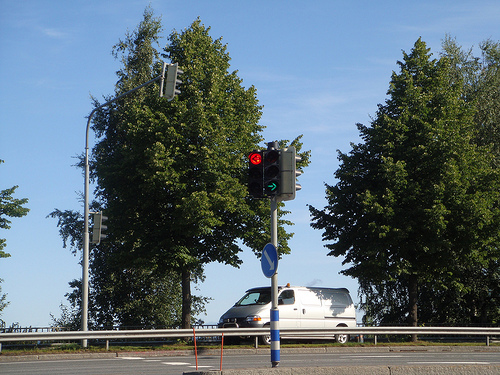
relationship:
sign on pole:
[259, 241, 279, 276] [263, 201, 281, 368]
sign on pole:
[259, 241, 279, 276] [79, 136, 94, 351]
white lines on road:
[118, 352, 210, 372] [0, 342, 497, 373]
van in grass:
[211, 277, 358, 345] [4, 337, 499, 344]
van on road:
[211, 277, 358, 345] [2, 315, 495, 368]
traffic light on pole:
[244, 146, 296, 203] [269, 201, 289, 366]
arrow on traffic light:
[264, 182, 277, 192] [216, 127, 293, 229]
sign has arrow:
[259, 241, 279, 276] [253, 234, 291, 279]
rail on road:
[4, 323, 498, 352] [10, 322, 472, 374]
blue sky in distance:
[1, 0, 498, 331] [6, 10, 498, 340]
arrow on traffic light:
[264, 182, 277, 192] [247, 145, 303, 200]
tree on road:
[101, 5, 312, 342] [2, 341, 499, 374]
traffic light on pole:
[159, 60, 178, 99] [78, 85, 153, 352]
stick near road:
[189, 321, 202, 373] [2, 322, 498, 371]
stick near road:
[214, 325, 229, 373] [2, 322, 498, 371]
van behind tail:
[216, 283, 358, 347] [0, 324, 498, 345]